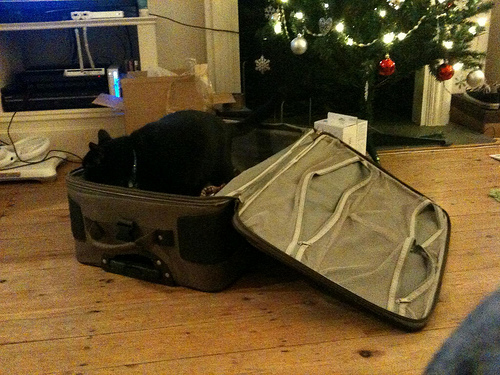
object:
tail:
[226, 84, 291, 140]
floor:
[0, 123, 500, 374]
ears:
[86, 139, 102, 152]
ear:
[95, 127, 112, 144]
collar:
[125, 144, 143, 190]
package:
[410, 59, 454, 128]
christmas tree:
[253, 0, 500, 131]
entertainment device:
[62, 9, 126, 80]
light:
[380, 30, 397, 47]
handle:
[80, 214, 160, 257]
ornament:
[288, 32, 310, 55]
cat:
[83, 84, 293, 197]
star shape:
[254, 56, 272, 73]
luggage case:
[62, 106, 452, 333]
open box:
[121, 64, 205, 135]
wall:
[148, 0, 241, 96]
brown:
[130, 81, 164, 106]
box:
[119, 62, 214, 136]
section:
[253, 54, 275, 77]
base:
[364, 124, 446, 167]